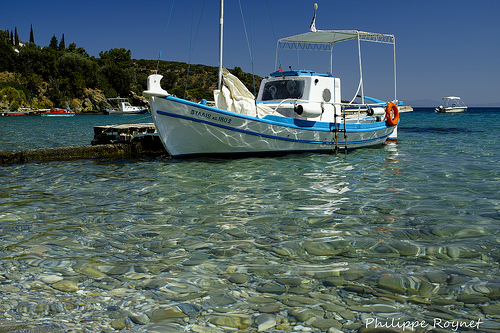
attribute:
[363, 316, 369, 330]
text — white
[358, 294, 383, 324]
text — white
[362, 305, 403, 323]
text — white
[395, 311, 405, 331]
text — white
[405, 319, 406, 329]
text — white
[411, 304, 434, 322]
text — white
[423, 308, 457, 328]
text — white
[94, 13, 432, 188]
boat — white, blue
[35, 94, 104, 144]
boat — red, white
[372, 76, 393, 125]
life saver — orange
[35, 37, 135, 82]
trees — PINE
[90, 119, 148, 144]
deck — WOOD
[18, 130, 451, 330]
water — CLEAR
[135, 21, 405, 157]
boat — WHITE, BLUE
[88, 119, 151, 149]
dock — WOODEN, SMALL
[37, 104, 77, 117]
boat — RED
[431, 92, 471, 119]
boat — WHITE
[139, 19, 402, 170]
boat — WHITE, BLUE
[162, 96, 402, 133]
trim — BLUE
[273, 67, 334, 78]
trim — BLUE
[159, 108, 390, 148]
trim — BLUE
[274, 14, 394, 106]
canopy — WHITE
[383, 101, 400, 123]
life preserver — ORANGE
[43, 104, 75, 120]
boat — RED, WHITE, SKI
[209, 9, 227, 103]
mast — METAL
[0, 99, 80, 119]
boat — red